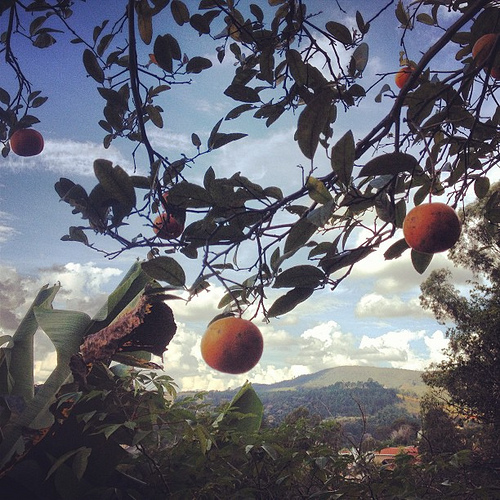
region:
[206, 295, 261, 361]
Orange on a tree branch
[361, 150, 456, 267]
Orange hanging from a tree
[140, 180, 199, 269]
two oranges together on a branch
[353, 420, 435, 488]
view of house in the distance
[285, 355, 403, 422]
Green mountain top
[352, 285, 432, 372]
group of clouds in the sky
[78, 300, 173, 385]
drying banana leaf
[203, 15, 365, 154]
leaves on a tree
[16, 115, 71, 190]
orange on a tree branch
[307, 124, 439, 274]
tree branches with oranges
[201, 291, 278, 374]
oranges in a tree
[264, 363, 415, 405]
a grass hill in the distance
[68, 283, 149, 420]
died leaf on a tree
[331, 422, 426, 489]
a town below the tree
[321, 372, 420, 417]
a wooded area on the hill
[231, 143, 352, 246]
a brown tree limb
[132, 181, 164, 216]
a small dark tree brach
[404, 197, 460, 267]
dark spots on a orange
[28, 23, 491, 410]
a furit tree with oranges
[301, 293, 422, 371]
a cloudy sky in the distance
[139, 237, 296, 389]
this is an orange on a tree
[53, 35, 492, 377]
this is an orange tree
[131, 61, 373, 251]
the tree has many green leaves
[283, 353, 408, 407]
there is a mountain in the background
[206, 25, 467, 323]
these are a few branches on the orange tree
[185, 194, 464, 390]
here are two of the several oranges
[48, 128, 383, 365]
the sky is blue with several clouds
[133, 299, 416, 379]
this clouded area is quite large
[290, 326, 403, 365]
the clouds are white in color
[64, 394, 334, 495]
here is a bunch of green leaves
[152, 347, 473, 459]
a hill in the countryside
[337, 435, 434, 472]
a couple houses at the bottom of the hill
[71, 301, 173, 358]
a brown leaf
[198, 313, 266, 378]
an orange on the orange tree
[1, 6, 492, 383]
a large orange tree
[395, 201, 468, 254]
this orange has brown spots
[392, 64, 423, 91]
this orange is small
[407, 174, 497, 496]
another large tree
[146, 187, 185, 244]
two oranges clumped together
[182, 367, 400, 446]
trees on the hill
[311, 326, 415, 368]
Large patch of white clouds in the sky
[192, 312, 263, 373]
Orange fruit growing on the tree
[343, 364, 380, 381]
Green hill in the background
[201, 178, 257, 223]
A group of green leaves on the tree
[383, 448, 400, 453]
Small part of a red roof of a house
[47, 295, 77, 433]
Large green leaf on a tree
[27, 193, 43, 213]
Small patch of the blue sky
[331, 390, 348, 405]
Green vegetation on hill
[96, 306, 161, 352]
Brown dead leaf on tree